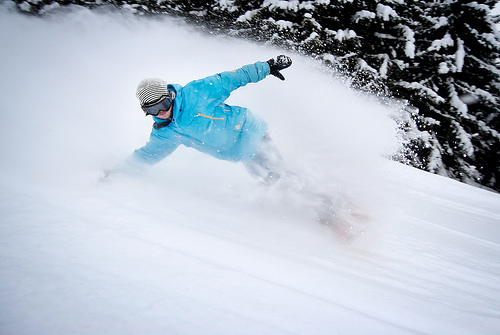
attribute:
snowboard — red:
[320, 155, 379, 263]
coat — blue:
[131, 60, 269, 162]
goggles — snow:
[138, 94, 175, 117]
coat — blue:
[115, 63, 275, 173]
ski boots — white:
[305, 185, 366, 235]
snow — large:
[11, 35, 489, 322]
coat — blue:
[119, 73, 360, 178]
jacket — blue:
[140, 50, 276, 202]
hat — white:
[134, 75, 171, 103]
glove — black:
[267, 55, 312, 75]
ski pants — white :
[230, 124, 364, 250]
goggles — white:
[140, 86, 179, 121]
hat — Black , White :
[133, 80, 186, 112]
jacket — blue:
[122, 54, 272, 172]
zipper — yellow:
[196, 112, 224, 121]